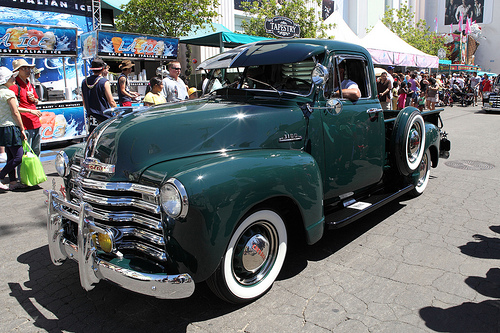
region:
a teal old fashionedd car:
[45, 48, 445, 306]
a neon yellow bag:
[15, 140, 47, 203]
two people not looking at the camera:
[1, 64, 44, 204]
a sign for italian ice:
[4, 28, 78, 53]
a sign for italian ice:
[96, 28, 182, 66]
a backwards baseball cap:
[89, 55, 106, 72]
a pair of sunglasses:
[172, 63, 182, 73]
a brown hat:
[117, 55, 138, 72]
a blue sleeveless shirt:
[79, 76, 121, 126]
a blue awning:
[187, 28, 262, 51]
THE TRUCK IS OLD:
[44, 35, 451, 316]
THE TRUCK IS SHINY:
[29, 27, 456, 315]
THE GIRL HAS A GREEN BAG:
[18, 137, 49, 194]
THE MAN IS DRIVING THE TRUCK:
[332, 64, 365, 111]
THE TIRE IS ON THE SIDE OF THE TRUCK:
[386, 103, 431, 190]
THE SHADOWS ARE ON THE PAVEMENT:
[4, 217, 499, 330]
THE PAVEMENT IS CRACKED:
[5, 137, 499, 331]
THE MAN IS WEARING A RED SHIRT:
[9, 80, 38, 134]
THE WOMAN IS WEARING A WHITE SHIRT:
[0, 87, 25, 127]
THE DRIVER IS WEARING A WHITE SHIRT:
[325, 58, 370, 105]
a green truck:
[50, 5, 497, 289]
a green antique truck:
[35, 10, 497, 324]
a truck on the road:
[67, 15, 479, 332]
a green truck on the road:
[47, 31, 499, 331]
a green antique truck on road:
[44, 28, 475, 281]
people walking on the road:
[12, 34, 283, 206]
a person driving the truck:
[276, 15, 392, 140]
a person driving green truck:
[246, 17, 476, 191]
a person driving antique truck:
[164, 28, 496, 250]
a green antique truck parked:
[54, 25, 335, 310]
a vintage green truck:
[65, 23, 446, 304]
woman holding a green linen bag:
[8, 133, 53, 191]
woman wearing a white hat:
[0, 61, 20, 82]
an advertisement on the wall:
[437, 0, 494, 26]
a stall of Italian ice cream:
[2, 16, 87, 132]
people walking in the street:
[377, 61, 480, 111]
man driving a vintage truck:
[295, 45, 370, 107]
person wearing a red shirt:
[477, 75, 492, 91]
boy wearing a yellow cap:
[185, 83, 200, 95]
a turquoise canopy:
[183, 22, 270, 47]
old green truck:
[32, 36, 451, 306]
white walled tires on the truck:
[210, 208, 297, 306]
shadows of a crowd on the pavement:
[410, 225, 498, 329]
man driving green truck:
[314, 45, 380, 124]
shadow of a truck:
[3, 240, 190, 330]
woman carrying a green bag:
[1, 66, 47, 195]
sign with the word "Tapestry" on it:
[262, 12, 302, 38]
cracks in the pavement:
[294, 280, 404, 328]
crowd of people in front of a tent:
[363, 22, 491, 102]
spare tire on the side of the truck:
[388, 105, 434, 179]